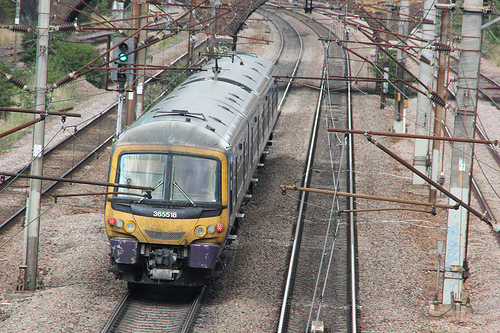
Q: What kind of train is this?
A: Passenger.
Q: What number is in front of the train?
A: 365510.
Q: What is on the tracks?
A: A train.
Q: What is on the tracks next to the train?
A: Nothing.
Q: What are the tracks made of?
A: Metal.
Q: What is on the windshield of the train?
A: Windshield wipers.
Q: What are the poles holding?
A: Electrical wires.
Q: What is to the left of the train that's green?
A: A light.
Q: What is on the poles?
A: Power lines.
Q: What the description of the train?
A: Tan roof.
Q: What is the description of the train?
A: Yellow front.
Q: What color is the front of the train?
A: Yellow.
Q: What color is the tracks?
A: Black.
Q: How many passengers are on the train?
A: Who Knows.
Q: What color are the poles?
A: Grey and white.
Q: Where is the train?
A: On the tracks.